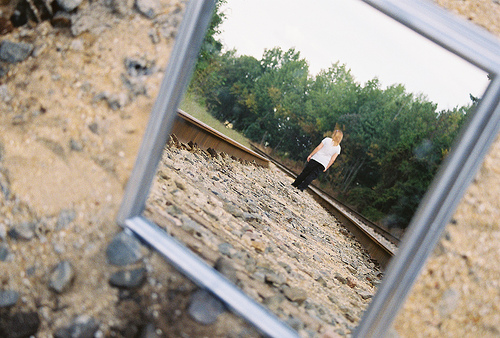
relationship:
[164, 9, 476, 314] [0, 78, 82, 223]
mirror on ground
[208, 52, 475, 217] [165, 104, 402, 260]
trees near tracks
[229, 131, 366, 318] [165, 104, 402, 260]
rocks near tracks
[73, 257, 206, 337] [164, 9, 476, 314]
rocks near mirror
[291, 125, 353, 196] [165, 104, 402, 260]
woman on tracks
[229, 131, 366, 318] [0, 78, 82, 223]
rocks on ground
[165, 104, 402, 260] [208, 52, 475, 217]
tracks near trees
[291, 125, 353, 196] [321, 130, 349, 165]
woman wears shirt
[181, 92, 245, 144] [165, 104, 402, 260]
grass near tracks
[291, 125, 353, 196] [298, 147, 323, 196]
woman wears pants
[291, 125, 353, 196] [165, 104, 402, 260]
woman walking on tracks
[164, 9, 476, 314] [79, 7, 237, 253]
mirror has frame